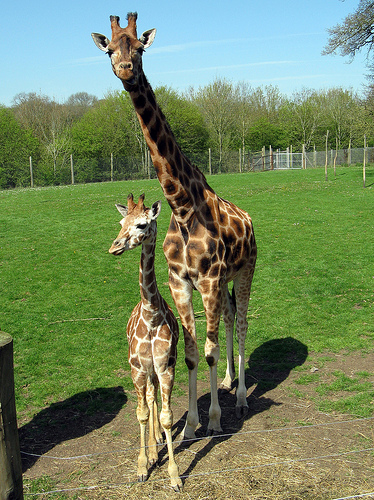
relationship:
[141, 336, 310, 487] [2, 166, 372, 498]
shadow on grass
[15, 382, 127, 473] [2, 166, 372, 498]
shadow on grass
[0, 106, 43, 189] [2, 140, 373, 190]
tree by fence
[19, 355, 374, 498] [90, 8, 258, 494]
patch of dirt by giraffes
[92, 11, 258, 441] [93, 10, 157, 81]
giraffe has head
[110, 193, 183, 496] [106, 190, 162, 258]
giraffe has head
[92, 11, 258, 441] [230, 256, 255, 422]
giraffe has leg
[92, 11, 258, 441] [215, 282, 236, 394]
giraffe has leg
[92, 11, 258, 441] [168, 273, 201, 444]
giraffe has leg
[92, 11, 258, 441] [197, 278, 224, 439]
giraffe has leg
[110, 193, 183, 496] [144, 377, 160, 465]
giraffe has leg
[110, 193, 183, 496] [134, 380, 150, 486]
giraffe has leg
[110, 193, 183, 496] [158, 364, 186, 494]
giraffe has leg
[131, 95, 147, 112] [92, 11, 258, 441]
spot on giraffe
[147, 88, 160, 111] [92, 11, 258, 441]
spot on giraffe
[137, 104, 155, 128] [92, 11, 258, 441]
spot on giraffe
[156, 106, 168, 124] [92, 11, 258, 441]
spot on giraffe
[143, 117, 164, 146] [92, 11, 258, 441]
spot on giraffe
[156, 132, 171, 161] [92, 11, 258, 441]
spot on giraffe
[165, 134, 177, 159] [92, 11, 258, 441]
spot on giraffe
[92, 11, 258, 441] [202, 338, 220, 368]
giraffe has knee